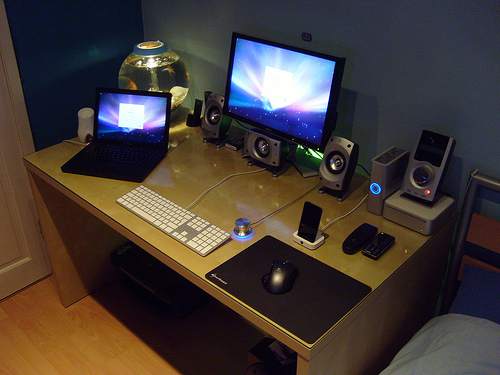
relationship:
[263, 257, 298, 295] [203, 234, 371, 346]
mouse on top of mouse pad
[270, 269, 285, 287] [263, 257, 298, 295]
glare on top of mouse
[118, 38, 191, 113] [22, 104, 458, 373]
fish bowl in corner of desk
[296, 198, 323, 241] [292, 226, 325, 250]
ipod charging in dock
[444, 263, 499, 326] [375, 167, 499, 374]
pillow on top of bed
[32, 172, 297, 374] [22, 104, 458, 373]
shadow underneath desk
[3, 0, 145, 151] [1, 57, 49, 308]
wall next to door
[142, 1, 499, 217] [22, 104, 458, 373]
wall behind desk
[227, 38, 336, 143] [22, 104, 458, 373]
screen on top of desk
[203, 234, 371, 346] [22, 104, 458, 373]
mouse pad on top of desk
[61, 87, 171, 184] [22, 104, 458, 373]
laptop on top of desk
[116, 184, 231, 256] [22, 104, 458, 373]
keyboard on top of desk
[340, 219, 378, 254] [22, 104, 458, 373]
remote control on top of desk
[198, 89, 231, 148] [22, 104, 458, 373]
speaker on top of desk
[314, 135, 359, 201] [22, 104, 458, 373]
speaker on top of desk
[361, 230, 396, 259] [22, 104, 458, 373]
cellphone on top of desk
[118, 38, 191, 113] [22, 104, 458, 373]
fish bowl on top of desk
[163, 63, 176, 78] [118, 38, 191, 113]
fish inside fish bowl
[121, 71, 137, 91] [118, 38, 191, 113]
fish inside fish bowl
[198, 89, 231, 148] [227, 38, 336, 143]
speaker beside screen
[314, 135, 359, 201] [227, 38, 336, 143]
speaker beside screen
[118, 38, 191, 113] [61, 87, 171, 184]
fish bowl next to laptop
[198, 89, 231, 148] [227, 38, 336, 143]
speaker next to screen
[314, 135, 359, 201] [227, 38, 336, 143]
speaker next to screen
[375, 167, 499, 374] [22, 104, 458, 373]
bed next to desk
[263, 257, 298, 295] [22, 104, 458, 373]
mouse sitting on desk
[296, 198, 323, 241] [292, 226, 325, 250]
ipod charging on dock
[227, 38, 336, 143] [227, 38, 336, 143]
screen of screen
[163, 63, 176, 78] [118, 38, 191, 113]
fish inside of fish bowl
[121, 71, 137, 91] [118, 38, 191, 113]
fish inside of fish bowl